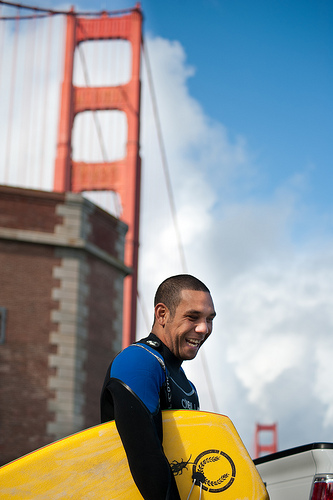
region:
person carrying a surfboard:
[0, 266, 280, 499]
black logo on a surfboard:
[166, 451, 200, 475]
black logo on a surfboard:
[186, 448, 239, 497]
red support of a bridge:
[247, 417, 282, 461]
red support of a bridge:
[39, 155, 143, 352]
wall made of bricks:
[0, 186, 137, 478]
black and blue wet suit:
[95, 334, 215, 499]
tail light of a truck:
[306, 471, 332, 499]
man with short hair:
[96, 264, 239, 499]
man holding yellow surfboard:
[99, 265, 242, 499]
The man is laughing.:
[148, 270, 236, 373]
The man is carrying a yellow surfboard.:
[19, 398, 240, 482]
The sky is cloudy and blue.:
[205, 178, 315, 368]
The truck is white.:
[257, 427, 324, 492]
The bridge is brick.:
[8, 250, 49, 413]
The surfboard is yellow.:
[39, 410, 254, 490]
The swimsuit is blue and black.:
[94, 332, 184, 409]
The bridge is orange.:
[55, 4, 142, 203]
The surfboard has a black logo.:
[179, 436, 238, 487]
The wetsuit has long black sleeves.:
[107, 382, 171, 485]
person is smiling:
[137, 261, 220, 371]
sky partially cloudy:
[161, 74, 321, 263]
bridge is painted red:
[53, 72, 140, 341]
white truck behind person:
[249, 437, 331, 499]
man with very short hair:
[93, 268, 234, 365]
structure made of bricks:
[0, 182, 126, 434]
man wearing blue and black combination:
[89, 271, 223, 482]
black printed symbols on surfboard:
[162, 429, 253, 499]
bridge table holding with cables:
[0, 72, 166, 245]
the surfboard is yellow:
[10, 400, 263, 488]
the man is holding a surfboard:
[66, 263, 268, 498]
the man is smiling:
[132, 263, 224, 376]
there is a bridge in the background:
[53, 63, 278, 455]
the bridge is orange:
[31, 0, 292, 457]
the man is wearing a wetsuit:
[79, 265, 237, 498]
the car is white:
[251, 421, 329, 496]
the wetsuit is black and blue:
[87, 332, 201, 411]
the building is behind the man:
[1, 192, 106, 368]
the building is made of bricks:
[8, 178, 86, 406]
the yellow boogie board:
[3, 407, 268, 499]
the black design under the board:
[168, 431, 242, 493]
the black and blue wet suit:
[102, 330, 216, 498]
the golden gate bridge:
[17, 113, 288, 460]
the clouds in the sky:
[204, 214, 323, 386]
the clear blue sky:
[215, 3, 328, 84]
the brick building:
[22, 202, 98, 403]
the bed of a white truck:
[248, 427, 330, 498]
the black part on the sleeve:
[121, 407, 180, 499]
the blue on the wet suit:
[121, 350, 150, 379]